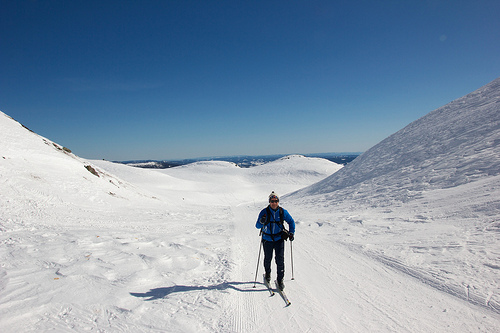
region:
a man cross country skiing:
[253, 191, 298, 308]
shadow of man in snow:
[129, 277, 267, 305]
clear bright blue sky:
[0, 0, 498, 160]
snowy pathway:
[222, 199, 496, 331]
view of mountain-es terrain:
[127, 153, 360, 169]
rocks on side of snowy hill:
[46, 140, 126, 200]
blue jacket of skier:
[255, 206, 297, 246]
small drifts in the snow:
[34, 224, 199, 319]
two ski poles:
[249, 235, 294, 288]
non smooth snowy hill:
[301, 79, 498, 319]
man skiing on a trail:
[245, 172, 319, 314]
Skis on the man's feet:
[255, 268, 302, 310]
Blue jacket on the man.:
[243, 196, 305, 246]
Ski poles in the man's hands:
[231, 216, 309, 293]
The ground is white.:
[2, 157, 496, 329]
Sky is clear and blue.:
[3, 15, 490, 171]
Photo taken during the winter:
[4, 5, 494, 327]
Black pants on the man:
[245, 231, 307, 292]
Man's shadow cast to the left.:
[110, 275, 288, 302]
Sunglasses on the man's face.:
[265, 197, 285, 206]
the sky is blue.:
[0, 1, 497, 178]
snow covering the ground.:
[0, 100, 499, 326]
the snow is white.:
[0, 93, 498, 328]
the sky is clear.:
[1, 2, 496, 144]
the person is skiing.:
[242, 185, 304, 305]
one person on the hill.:
[245, 179, 307, 309]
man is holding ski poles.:
[247, 218, 300, 290]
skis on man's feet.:
[258, 266, 294, 307]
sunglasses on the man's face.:
[262, 192, 282, 204]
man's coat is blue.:
[249, 202, 299, 247]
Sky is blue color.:
[81, 36, 233, 106]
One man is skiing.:
[239, 182, 321, 294]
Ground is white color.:
[26, 188, 123, 288]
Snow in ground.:
[39, 188, 129, 278]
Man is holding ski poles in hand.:
[247, 218, 307, 288]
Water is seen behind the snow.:
[161, 151, 368, 174]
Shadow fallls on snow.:
[137, 266, 287, 312]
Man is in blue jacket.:
[250, 208, 297, 243]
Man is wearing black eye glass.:
[261, 193, 288, 210]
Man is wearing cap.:
[260, 186, 282, 216]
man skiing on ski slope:
[243, 187, 301, 317]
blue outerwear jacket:
[247, 207, 298, 244]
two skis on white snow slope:
[253, 268, 293, 310]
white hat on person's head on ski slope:
[264, 186, 280, 198]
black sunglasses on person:
[265, 198, 283, 205]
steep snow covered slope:
[296, 72, 495, 320]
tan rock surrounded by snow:
[77, 161, 111, 186]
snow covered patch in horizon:
[121, 161, 161, 170]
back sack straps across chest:
[258, 210, 285, 227]